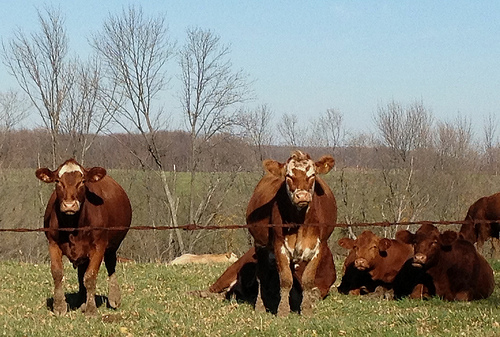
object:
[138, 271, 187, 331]
field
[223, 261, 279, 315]
shadow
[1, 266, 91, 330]
field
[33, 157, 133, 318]
cow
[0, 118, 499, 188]
land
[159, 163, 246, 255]
branch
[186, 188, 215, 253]
twig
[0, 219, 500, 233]
wire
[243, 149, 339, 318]
cow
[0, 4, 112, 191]
trees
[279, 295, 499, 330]
grass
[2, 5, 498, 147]
sky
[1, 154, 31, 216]
meadow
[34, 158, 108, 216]
head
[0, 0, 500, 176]
background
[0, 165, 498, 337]
field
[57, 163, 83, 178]
spot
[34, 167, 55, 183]
ears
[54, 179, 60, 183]
eye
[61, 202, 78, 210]
nose